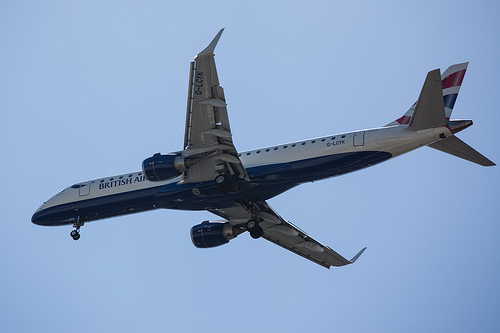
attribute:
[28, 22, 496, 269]
plane — blue, flying, british, white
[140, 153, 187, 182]
engine — blue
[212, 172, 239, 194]
landing gear — down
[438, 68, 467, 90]
stripe — red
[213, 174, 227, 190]
wheel — black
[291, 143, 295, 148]
window — round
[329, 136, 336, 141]
window — round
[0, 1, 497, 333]
air — blue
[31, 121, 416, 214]
side — white